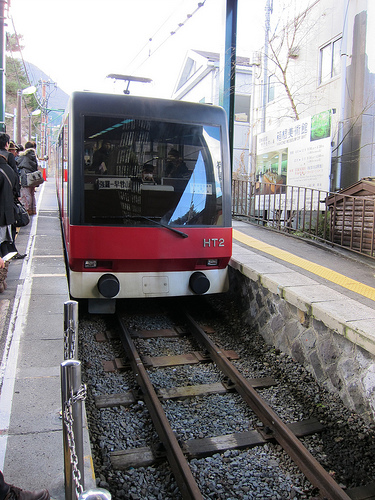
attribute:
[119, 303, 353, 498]
train tracks — brown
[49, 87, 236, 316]
train — metal, red, black, white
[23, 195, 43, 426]
lines — white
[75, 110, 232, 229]
window — big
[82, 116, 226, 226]
window — big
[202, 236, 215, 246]
letters — silver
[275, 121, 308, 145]
letters — silver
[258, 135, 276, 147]
letters — silver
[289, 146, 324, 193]
letters — silver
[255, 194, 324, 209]
letters — silver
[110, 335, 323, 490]
tracks — wooden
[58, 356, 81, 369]
ring — metal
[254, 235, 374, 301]
yellow line — thick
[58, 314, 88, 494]
chain — silver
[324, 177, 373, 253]
house — brown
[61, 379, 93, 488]
chain — metal